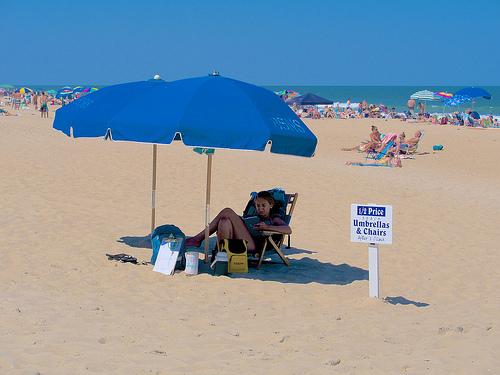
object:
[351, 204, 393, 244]
sign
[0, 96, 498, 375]
beach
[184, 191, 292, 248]
woman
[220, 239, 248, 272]
bag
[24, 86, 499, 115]
ocean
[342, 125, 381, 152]
people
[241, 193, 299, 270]
chair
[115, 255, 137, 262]
sandals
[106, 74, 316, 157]
canopy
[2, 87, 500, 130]
families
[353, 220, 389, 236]
writing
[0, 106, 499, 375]
sand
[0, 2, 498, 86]
sky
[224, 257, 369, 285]
shadow